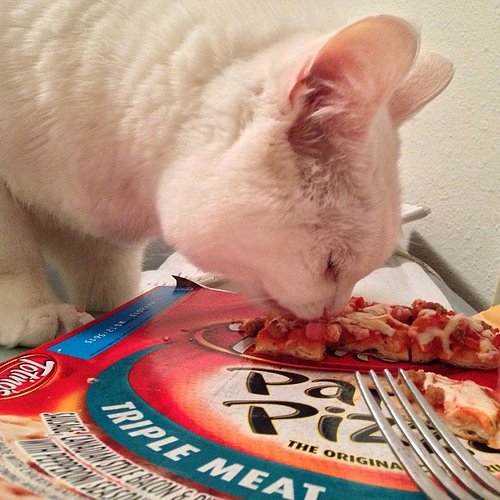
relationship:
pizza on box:
[239, 295, 500, 371] [14, 277, 474, 498]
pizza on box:
[390, 367, 499, 444] [14, 277, 474, 498]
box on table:
[0, 201, 497, 499] [1, 0, 496, 499]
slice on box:
[251, 293, 452, 392] [57, 278, 455, 493]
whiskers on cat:
[207, 292, 296, 327] [1, 2, 455, 349]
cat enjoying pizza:
[1, 2, 455, 349] [270, 287, 490, 375]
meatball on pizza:
[421, 300, 448, 315] [251, 289, 482, 445]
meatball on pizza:
[266, 315, 290, 337] [251, 289, 482, 445]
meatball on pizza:
[424, 384, 446, 409] [251, 289, 482, 445]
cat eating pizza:
[0, 0, 457, 349] [239, 295, 500, 371]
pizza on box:
[239, 290, 499, 377] [14, 277, 474, 498]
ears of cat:
[281, 13, 454, 155] [1, 2, 455, 349]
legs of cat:
[12, 249, 106, 309] [95, 31, 397, 293]